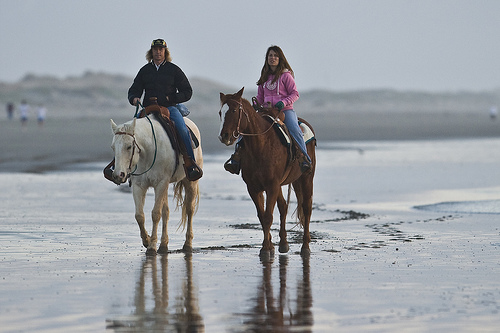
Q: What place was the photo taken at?
A: It was taken at the beach.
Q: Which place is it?
A: It is a beach.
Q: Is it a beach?
A: Yes, it is a beach.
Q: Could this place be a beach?
A: Yes, it is a beach.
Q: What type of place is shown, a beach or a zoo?
A: It is a beach.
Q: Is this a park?
A: No, it is a beach.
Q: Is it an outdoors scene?
A: Yes, it is outdoors.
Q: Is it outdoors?
A: Yes, it is outdoors.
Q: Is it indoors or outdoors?
A: It is outdoors.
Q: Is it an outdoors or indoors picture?
A: It is outdoors.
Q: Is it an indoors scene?
A: No, it is outdoors.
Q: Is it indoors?
A: No, it is outdoors.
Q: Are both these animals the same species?
A: Yes, all the animals are horses.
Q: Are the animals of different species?
A: No, all the animals are horses.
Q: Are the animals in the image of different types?
A: No, all the animals are horses.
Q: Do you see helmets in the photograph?
A: No, there are no helmets.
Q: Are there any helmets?
A: No, there are no helmets.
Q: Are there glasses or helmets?
A: No, there are no helmets or glasses.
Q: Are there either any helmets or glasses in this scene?
A: No, there are no helmets or glasses.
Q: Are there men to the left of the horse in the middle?
A: Yes, there is a man to the left of the horse.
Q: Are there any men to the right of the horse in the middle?
A: No, the man is to the left of the horse.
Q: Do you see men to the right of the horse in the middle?
A: No, the man is to the left of the horse.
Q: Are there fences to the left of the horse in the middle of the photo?
A: No, there is a man to the left of the horse.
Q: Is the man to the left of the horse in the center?
A: Yes, the man is to the left of the horse.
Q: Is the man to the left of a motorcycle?
A: No, the man is to the left of the horse.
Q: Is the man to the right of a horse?
A: No, the man is to the left of a horse.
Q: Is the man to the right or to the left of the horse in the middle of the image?
A: The man is to the left of the horse.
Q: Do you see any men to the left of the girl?
A: Yes, there is a man to the left of the girl.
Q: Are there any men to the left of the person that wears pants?
A: Yes, there is a man to the left of the girl.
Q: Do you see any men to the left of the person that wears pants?
A: Yes, there is a man to the left of the girl.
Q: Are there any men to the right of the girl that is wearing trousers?
A: No, the man is to the left of the girl.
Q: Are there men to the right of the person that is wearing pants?
A: No, the man is to the left of the girl.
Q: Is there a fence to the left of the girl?
A: No, there is a man to the left of the girl.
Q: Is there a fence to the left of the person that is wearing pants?
A: No, there is a man to the left of the girl.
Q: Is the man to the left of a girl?
A: Yes, the man is to the left of a girl.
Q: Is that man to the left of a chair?
A: No, the man is to the left of a girl.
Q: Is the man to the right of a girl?
A: No, the man is to the left of a girl.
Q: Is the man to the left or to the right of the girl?
A: The man is to the left of the girl.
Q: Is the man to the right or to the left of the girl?
A: The man is to the left of the girl.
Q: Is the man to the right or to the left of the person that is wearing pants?
A: The man is to the left of the girl.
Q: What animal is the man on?
A: The man is on the horse.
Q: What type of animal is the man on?
A: The man is on the horse.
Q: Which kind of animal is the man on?
A: The man is on the horse.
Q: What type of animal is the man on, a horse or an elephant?
A: The man is on a horse.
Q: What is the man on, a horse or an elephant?
A: The man is on a horse.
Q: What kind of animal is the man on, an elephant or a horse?
A: The man is on a horse.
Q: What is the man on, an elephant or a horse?
A: The man is on a horse.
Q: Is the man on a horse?
A: Yes, the man is on a horse.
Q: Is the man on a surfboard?
A: No, the man is on a horse.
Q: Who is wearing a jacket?
A: The man is wearing a jacket.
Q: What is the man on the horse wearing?
A: The man is wearing a jacket.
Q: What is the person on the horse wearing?
A: The man is wearing a jacket.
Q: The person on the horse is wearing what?
A: The man is wearing a jacket.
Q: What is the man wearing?
A: The man is wearing a jacket.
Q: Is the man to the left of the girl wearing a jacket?
A: Yes, the man is wearing a jacket.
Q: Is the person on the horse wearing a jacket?
A: Yes, the man is wearing a jacket.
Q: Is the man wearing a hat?
A: No, the man is wearing a jacket.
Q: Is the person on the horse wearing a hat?
A: No, the man is wearing a jacket.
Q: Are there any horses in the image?
A: Yes, there is a horse.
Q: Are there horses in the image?
A: Yes, there is a horse.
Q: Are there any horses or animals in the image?
A: Yes, there is a horse.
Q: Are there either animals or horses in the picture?
A: Yes, there is a horse.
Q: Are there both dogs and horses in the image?
A: No, there is a horse but no dogs.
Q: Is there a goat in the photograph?
A: No, there are no goats.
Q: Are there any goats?
A: No, there are no goats.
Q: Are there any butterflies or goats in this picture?
A: No, there are no goats or butterflies.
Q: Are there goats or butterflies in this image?
A: No, there are no goats or butterflies.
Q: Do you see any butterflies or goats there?
A: No, there are no goats or butterflies.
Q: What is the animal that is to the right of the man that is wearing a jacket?
A: The animal is a horse.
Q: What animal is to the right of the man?
A: The animal is a horse.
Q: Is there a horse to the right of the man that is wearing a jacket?
A: Yes, there is a horse to the right of the man.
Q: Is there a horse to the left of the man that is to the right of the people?
A: No, the horse is to the right of the man.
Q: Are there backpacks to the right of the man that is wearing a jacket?
A: No, there is a horse to the right of the man.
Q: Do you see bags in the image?
A: No, there are no bags.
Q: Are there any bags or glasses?
A: No, there are no bags or glasses.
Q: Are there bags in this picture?
A: No, there are no bags.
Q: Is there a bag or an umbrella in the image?
A: No, there are no bags or umbrellas.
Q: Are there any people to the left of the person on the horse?
A: Yes, there are people to the left of the man.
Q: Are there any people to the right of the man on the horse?
A: No, the people are to the left of the man.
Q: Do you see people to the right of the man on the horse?
A: No, the people are to the left of the man.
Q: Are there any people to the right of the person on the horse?
A: No, the people are to the left of the man.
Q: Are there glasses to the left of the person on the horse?
A: No, there are people to the left of the man.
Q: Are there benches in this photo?
A: No, there are no benches.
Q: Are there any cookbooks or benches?
A: No, there are no benches or cookbooks.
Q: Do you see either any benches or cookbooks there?
A: No, there are no benches or cookbooks.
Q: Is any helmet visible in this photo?
A: No, there are no helmets.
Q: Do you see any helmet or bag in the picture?
A: No, there are no helmets or bags.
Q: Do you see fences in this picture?
A: No, there are no fences.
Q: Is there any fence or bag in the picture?
A: No, there are no fences or bags.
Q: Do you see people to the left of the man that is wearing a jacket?
A: Yes, there are people to the left of the man.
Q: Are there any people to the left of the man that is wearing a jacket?
A: Yes, there are people to the left of the man.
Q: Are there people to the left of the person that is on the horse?
A: Yes, there are people to the left of the man.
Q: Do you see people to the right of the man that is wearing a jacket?
A: No, the people are to the left of the man.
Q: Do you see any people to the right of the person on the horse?
A: No, the people are to the left of the man.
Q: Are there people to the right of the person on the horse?
A: No, the people are to the left of the man.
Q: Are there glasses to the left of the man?
A: No, there are people to the left of the man.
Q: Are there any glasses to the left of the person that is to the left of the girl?
A: No, there are people to the left of the man.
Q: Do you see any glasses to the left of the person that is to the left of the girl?
A: No, there are people to the left of the man.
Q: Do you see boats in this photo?
A: No, there are no boats.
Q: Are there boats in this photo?
A: No, there are no boats.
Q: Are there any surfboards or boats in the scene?
A: No, there are no boats or surfboards.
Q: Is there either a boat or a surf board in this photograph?
A: No, there are no boats or surfboards.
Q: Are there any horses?
A: Yes, there is a horse.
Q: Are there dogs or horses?
A: Yes, there is a horse.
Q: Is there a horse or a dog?
A: Yes, there is a horse.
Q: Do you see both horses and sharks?
A: No, there is a horse but no sharks.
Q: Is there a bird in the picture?
A: No, there are no birds.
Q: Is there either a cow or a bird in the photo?
A: No, there are no birds or cows.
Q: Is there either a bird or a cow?
A: No, there are no birds or cows.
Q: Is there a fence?
A: No, there are no fences.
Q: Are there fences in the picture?
A: No, there are no fences.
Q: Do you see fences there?
A: No, there are no fences.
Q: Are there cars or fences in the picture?
A: No, there are no fences or cars.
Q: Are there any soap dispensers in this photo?
A: No, there are no soap dispensers.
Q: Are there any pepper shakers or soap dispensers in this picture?
A: No, there are no soap dispensers or pepper shakers.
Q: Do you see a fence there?
A: No, there are no fences.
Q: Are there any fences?
A: No, there are no fences.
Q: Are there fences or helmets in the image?
A: No, there are no fences or helmets.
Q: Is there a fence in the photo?
A: No, there are no fences.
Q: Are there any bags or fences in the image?
A: No, there are no fences or bags.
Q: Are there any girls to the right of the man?
A: Yes, there is a girl to the right of the man.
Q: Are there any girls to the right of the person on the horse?
A: Yes, there is a girl to the right of the man.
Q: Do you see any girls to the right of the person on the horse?
A: Yes, there is a girl to the right of the man.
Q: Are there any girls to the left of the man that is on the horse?
A: No, the girl is to the right of the man.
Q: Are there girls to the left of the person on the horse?
A: No, the girl is to the right of the man.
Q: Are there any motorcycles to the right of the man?
A: No, there is a girl to the right of the man.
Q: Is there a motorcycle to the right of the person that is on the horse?
A: No, there is a girl to the right of the man.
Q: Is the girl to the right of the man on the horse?
A: Yes, the girl is to the right of the man.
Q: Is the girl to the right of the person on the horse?
A: Yes, the girl is to the right of the man.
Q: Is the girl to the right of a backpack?
A: No, the girl is to the right of the man.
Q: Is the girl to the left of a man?
A: No, the girl is to the right of a man.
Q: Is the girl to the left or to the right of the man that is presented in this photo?
A: The girl is to the right of the man.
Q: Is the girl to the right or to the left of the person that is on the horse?
A: The girl is to the right of the man.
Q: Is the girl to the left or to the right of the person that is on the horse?
A: The girl is to the right of the man.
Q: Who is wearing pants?
A: The girl is wearing pants.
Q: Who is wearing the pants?
A: The girl is wearing pants.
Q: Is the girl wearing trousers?
A: Yes, the girl is wearing trousers.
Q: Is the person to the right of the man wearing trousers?
A: Yes, the girl is wearing trousers.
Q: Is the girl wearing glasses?
A: No, the girl is wearing trousers.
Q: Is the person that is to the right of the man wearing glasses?
A: No, the girl is wearing trousers.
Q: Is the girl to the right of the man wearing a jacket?
A: Yes, the girl is wearing a jacket.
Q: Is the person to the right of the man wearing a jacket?
A: Yes, the girl is wearing a jacket.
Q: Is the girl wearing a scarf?
A: No, the girl is wearing a jacket.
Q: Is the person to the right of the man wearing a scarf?
A: No, the girl is wearing a jacket.